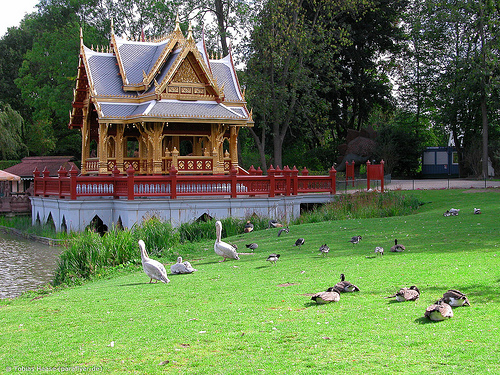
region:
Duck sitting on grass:
[387, 281, 422, 305]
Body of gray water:
[0, 222, 83, 306]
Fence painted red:
[361, 157, 392, 194]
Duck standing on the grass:
[205, 217, 239, 267]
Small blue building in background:
[413, 139, 483, 181]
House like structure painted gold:
[65, 24, 255, 174]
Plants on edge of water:
[55, 209, 175, 297]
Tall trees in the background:
[0, 0, 493, 169]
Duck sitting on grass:
[470, 205, 482, 217]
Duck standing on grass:
[128, 238, 170, 287]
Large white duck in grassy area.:
[127, 238, 202, 332]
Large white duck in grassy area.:
[206, 200, 243, 286]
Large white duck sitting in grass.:
[173, 245, 211, 311]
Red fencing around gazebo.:
[81, 165, 250, 197]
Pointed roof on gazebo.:
[83, 38, 305, 178]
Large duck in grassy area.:
[126, 232, 177, 302]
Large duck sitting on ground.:
[171, 243, 204, 291]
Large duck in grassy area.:
[205, 221, 262, 290]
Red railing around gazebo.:
[54, 153, 286, 194]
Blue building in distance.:
[417, 137, 488, 227]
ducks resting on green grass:
[305, 266, 482, 336]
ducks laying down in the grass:
[306, 270, 467, 325]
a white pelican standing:
[205, 217, 236, 265]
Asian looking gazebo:
[23, 20, 335, 220]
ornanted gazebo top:
[140, 10, 230, 110]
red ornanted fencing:
[26, 165, 346, 200]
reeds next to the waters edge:
[2, 225, 118, 290]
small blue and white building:
[415, 142, 470, 178]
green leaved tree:
[251, 0, 319, 162]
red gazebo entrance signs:
[342, 153, 387, 195]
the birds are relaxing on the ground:
[309, 200, 484, 337]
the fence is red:
[163, 164, 325, 199]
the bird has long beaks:
[200, 215, 245, 269]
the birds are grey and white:
[289, 231, 471, 327]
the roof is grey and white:
[96, 40, 255, 123]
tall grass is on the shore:
[95, 218, 185, 250]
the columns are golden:
[88, 125, 248, 166]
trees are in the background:
[255, 28, 492, 142]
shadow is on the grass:
[441, 280, 498, 302]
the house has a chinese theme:
[78, 20, 253, 192]